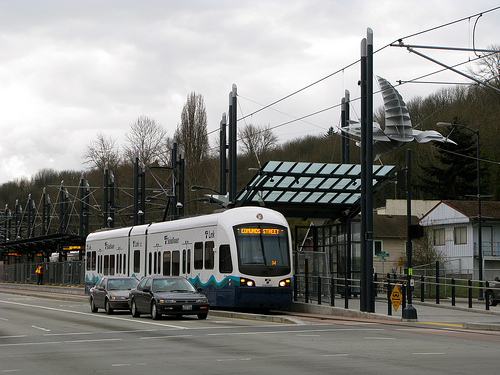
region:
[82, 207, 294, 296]
the train is at the station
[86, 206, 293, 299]
the train is white in color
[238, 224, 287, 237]
a sign is on the train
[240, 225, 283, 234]
the sign is lit brightly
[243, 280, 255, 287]
the headlight is turned on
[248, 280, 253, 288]
the light is white in color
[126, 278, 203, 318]
a car is besides the train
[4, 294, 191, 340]
a line runs along the road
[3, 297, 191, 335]
the line is white in color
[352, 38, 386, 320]
a pole is in front and besides the train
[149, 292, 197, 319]
a head light to the car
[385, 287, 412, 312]
a yellow, and black sign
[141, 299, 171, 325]
a black tire on a car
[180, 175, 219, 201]
a light on a pole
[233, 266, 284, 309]
a head light to a bus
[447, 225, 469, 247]
a window to a building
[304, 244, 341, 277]
a fence near the bus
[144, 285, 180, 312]
a black car going down road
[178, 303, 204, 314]
a tag on front of car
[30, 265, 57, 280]
a man standing in the distance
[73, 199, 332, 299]
the train on the street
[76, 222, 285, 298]
the train is white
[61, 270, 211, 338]
the cars on the street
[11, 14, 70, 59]
the sky is gray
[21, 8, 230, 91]
the clouds in the sky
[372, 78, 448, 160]
the modern sculpture above the houses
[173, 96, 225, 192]
the trees are bare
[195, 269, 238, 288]
the blue wave on the bus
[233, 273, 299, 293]
the lights on the bus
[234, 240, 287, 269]
the windshield of the bus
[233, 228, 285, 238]
digital display on the front of a bus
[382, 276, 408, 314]
yellow and black sign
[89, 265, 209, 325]
two cars beside a bus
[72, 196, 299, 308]
bus parked at a bus stop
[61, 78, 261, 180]
tree tops towering over wires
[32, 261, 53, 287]
person on the side of the road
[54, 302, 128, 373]
white lines on the pavement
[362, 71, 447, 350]
decorative street lamp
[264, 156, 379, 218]
windowed roof to a bus shelter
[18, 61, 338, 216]
rows of trees lining the street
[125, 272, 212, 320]
Car is stopped in the street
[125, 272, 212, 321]
Car is stopped in the road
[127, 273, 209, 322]
Black car is stopped in the street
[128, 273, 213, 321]
Black car is stopped in the road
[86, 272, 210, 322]
Cars are stopped in the street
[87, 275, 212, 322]
Cars are stopped in the road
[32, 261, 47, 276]
Man is wearing a vest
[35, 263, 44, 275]
Man is wearing a reflective vest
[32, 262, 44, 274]
Man is wearing an orange vest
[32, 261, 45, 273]
Man is wearing a reflective orange vest